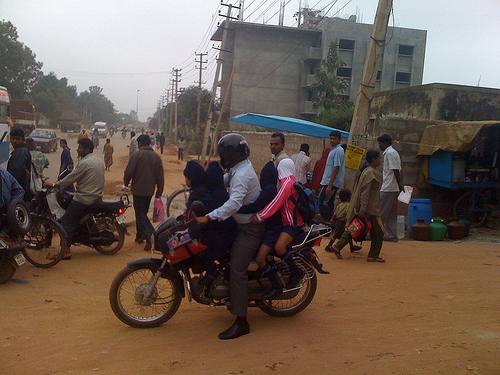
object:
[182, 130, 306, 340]
four people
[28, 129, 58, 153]
cars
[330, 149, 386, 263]
woman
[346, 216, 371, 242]
bag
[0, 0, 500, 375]
town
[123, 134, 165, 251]
person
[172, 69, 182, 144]
pole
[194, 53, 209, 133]
pole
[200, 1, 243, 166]
pole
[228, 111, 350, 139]
awning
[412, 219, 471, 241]
pots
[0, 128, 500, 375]
road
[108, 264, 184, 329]
tire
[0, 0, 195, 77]
sky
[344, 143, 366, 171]
sign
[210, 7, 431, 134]
building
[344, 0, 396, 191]
eletrical poles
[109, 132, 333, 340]
man rides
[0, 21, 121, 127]
trees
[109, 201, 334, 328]
motor cycle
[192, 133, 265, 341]
man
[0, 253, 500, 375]
ground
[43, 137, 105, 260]
man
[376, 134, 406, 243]
person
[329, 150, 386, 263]
person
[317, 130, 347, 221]
person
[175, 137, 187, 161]
person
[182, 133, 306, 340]
family